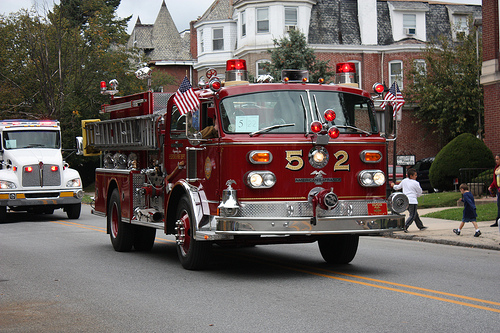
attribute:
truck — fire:
[88, 57, 397, 268]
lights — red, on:
[224, 45, 361, 89]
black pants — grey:
[406, 203, 426, 230]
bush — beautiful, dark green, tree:
[431, 131, 496, 193]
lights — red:
[242, 165, 385, 192]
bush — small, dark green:
[425, 128, 497, 195]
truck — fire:
[111, 57, 361, 262]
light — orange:
[244, 149, 278, 162]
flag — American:
[356, 73, 427, 150]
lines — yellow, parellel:
[246, 251, 498, 308]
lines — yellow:
[360, 272, 499, 324]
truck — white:
[0, 115, 87, 219]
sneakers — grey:
[453, 228, 479, 238]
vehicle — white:
[1, 116, 88, 219]